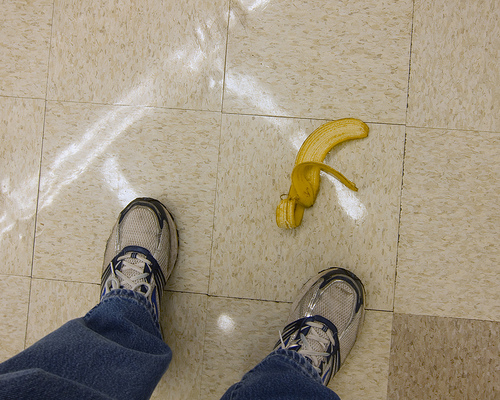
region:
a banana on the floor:
[263, 94, 373, 236]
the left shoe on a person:
[94, 194, 181, 330]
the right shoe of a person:
[272, 271, 372, 398]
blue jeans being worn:
[9, 287, 335, 396]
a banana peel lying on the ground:
[275, 164, 362, 234]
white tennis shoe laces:
[284, 324, 336, 366]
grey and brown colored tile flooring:
[39, 94, 284, 182]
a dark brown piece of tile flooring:
[388, 309, 498, 397]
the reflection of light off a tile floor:
[61, 23, 292, 125]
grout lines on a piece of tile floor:
[388, 6, 416, 311]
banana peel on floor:
[266, 97, 371, 242]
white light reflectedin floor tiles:
[202, 60, 299, 152]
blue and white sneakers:
[92, 189, 377, 389]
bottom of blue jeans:
[1, 280, 349, 395]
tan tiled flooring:
[1, 3, 494, 142]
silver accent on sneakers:
[303, 285, 320, 320]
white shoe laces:
[276, 309, 338, 374]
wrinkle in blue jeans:
[72, 307, 177, 373]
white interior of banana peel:
[313, 128, 344, 150]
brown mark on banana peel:
[301, 182, 314, 201]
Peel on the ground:
[265, 108, 380, 233]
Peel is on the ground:
[270, 114, 378, 235]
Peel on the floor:
[267, 112, 383, 238]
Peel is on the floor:
[271, 112, 378, 237]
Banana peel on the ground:
[270, 112, 380, 233]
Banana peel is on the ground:
[270, 115, 380, 237]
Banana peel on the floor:
[275, 117, 379, 237]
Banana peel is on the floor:
[266, 108, 383, 238]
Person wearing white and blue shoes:
[85, 186, 377, 393]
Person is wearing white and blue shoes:
[89, 196, 372, 386]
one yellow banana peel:
[274, 114, 374, 234]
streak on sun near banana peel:
[226, 77, 381, 245]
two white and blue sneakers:
[68, 193, 390, 375]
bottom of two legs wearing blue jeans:
[28, 195, 381, 399]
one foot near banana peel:
[266, 99, 371, 369]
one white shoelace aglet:
[276, 329, 286, 351]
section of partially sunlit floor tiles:
[20, 16, 264, 191]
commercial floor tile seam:
[379, 125, 419, 317]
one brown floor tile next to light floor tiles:
[373, 296, 495, 399]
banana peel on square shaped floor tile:
[201, 109, 408, 264]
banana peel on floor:
[266, 113, 372, 232]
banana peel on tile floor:
[255, 108, 378, 229]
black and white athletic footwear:
[87, 188, 371, 381]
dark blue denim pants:
[2, 285, 347, 399]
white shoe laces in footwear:
[100, 250, 333, 382]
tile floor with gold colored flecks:
[1, 3, 498, 399]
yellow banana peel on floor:
[267, 111, 375, 233]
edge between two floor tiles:
[382, 123, 409, 315]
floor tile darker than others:
[379, 307, 496, 399]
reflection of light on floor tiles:
[4, 1, 372, 343]